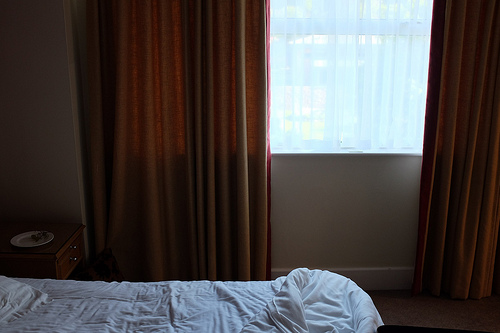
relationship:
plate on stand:
[11, 222, 48, 247] [0, 215, 100, 275]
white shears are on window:
[267, 0, 434, 161] [267, 2, 436, 159]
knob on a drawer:
[69, 252, 83, 264] [56, 242, 91, 277]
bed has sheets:
[1, 267, 383, 331] [18, 270, 371, 331]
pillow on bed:
[274, 263, 389, 332] [0, 261, 380, 327]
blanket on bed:
[2, 270, 374, 331] [0, 261, 380, 327]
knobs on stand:
[71, 239, 81, 264] [9, 200, 93, 278]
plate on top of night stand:
[10, 227, 67, 262] [2, 212, 97, 279]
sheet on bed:
[247, 263, 387, 331] [1, 257, 386, 330]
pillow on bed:
[0, 271, 52, 327] [1, 257, 386, 330]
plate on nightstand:
[4, 224, 57, 252] [3, 211, 85, 278]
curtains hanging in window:
[71, 0, 485, 302] [267, 2, 436, 159]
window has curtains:
[267, 2, 436, 159] [71, 0, 485, 302]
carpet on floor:
[404, 303, 456, 320] [368, 284, 485, 331]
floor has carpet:
[368, 284, 485, 331] [404, 303, 456, 320]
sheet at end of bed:
[245, 295, 316, 332] [31, 270, 253, 330]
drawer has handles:
[63, 230, 175, 282] [32, 249, 136, 290]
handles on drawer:
[32, 249, 136, 290] [63, 230, 175, 282]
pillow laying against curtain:
[70, 241, 126, 277] [80, 3, 269, 276]